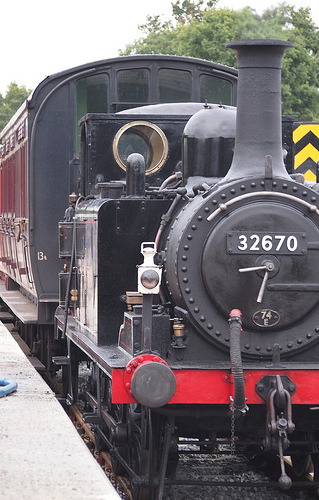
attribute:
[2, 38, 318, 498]
train — red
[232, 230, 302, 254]
number — large, written, white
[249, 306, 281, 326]
number — 74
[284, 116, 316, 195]
sign — yellow, black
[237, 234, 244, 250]
number — white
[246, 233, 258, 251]
number — white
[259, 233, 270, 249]
number — white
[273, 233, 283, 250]
number — white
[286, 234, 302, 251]
number — white